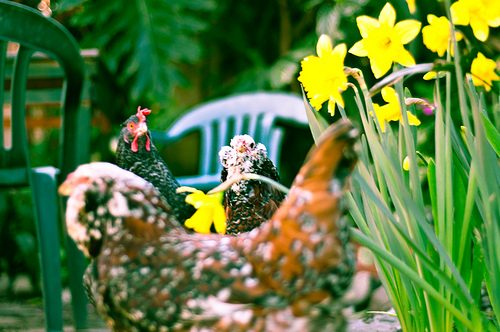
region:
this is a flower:
[288, 37, 393, 132]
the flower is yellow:
[292, 25, 362, 130]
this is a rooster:
[105, 95, 210, 225]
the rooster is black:
[130, 97, 151, 122]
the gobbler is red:
[125, 130, 159, 158]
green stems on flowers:
[343, 70, 480, 307]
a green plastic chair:
[8, 5, 108, 327]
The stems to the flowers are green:
[371, 100, 495, 326]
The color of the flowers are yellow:
[292, 0, 496, 113]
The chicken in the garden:
[91, 88, 187, 216]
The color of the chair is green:
[2, 1, 93, 329]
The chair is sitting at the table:
[9, 4, 98, 330]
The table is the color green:
[7, 38, 137, 235]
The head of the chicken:
[113, 99, 163, 153]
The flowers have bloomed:
[301, 4, 493, 118]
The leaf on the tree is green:
[78, 0, 223, 97]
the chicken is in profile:
[45, 107, 361, 328]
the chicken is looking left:
[114, 108, 186, 228]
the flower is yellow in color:
[352, 2, 422, 74]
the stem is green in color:
[390, 59, 420, 217]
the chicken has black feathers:
[117, 115, 189, 215]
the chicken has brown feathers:
[71, 125, 358, 330]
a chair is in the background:
[159, 86, 336, 233]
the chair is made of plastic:
[0, 1, 91, 326]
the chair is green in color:
[0, 0, 95, 327]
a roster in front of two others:
[34, 158, 399, 325]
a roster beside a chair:
[108, 107, 165, 170]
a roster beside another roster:
[198, 130, 273, 199]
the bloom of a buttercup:
[283, 31, 347, 113]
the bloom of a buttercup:
[168, 182, 238, 241]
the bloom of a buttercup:
[468, 49, 497, 99]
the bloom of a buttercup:
[453, 0, 499, 50]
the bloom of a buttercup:
[353, 0, 423, 88]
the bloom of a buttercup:
[366, 88, 413, 133]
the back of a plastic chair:
[3, 5, 84, 323]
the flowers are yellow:
[297, 10, 414, 105]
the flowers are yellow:
[297, 10, 433, 82]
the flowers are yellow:
[295, 12, 473, 114]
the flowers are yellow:
[298, 12, 450, 118]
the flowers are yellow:
[302, 8, 434, 106]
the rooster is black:
[96, 112, 180, 192]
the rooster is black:
[103, 95, 183, 196]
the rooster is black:
[99, 94, 168, 185]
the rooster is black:
[97, 97, 179, 218]